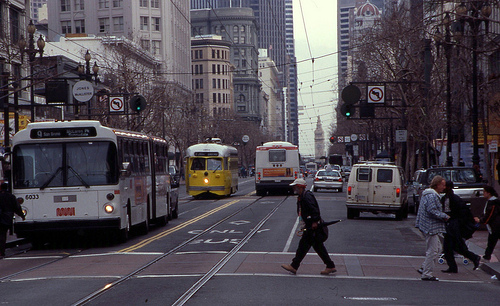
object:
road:
[9, 161, 498, 304]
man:
[282, 175, 342, 275]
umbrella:
[293, 213, 344, 237]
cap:
[289, 178, 307, 188]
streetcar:
[182, 136, 241, 199]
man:
[415, 167, 453, 282]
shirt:
[415, 183, 449, 238]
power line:
[11, 54, 467, 102]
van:
[340, 156, 412, 219]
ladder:
[357, 164, 371, 203]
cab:
[313, 169, 344, 193]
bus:
[8, 118, 182, 248]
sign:
[364, 84, 389, 105]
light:
[345, 112, 352, 117]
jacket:
[296, 189, 321, 230]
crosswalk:
[0, 250, 488, 287]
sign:
[106, 96, 130, 112]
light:
[135, 97, 142, 111]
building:
[189, 31, 241, 170]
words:
[186, 219, 268, 245]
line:
[91, 166, 283, 275]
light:
[104, 204, 114, 214]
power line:
[24, 2, 477, 167]